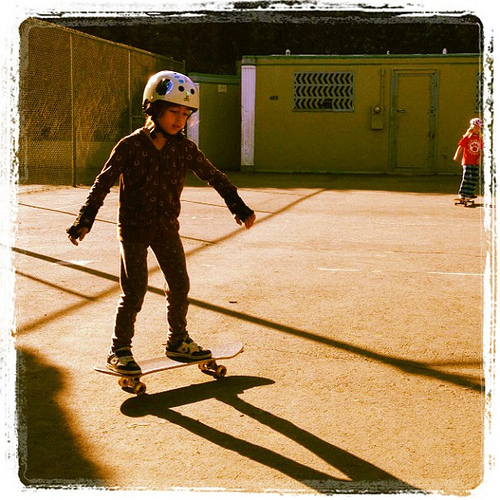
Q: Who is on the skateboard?
A: Girl.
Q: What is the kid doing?
A: Riding a skateboard.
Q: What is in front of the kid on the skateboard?
A: Shadow.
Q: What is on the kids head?
A: Helmet.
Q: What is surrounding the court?
A: Fence.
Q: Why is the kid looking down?
A: Focusing.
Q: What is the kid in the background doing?
A: Skateboarding.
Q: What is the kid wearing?
A: Jacket and pants.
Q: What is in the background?
A: Building.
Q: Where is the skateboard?
A: On the ground.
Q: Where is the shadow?
A: On the ground.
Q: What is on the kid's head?
A: A helmet.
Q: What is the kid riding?
A: A board.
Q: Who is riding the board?
A: A kid.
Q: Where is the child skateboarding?
A: In a parking lot.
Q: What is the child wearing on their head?
A: A helmet.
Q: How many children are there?
A: Two.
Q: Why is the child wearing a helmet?
A: To avoid injury.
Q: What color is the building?
A: Green.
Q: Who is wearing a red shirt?
A: A child in the background.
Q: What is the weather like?
A: It is sunny.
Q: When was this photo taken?
A: During the day.